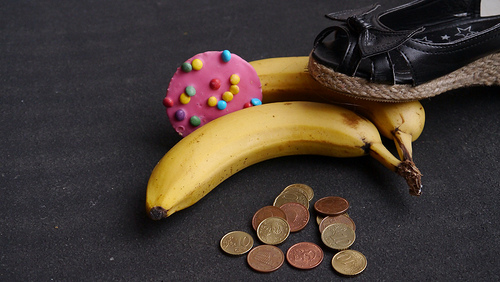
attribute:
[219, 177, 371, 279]
pennies — pile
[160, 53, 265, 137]
cookie — pink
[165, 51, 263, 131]
frosting — pink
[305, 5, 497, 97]
shoe — black, brown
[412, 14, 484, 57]
stars — white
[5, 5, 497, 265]
table — black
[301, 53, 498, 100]
trim — fabric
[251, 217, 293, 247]
coin — gold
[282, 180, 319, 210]
coin — gold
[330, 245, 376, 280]
coin — copper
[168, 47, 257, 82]
cupcake — half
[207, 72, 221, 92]
sprinkle — red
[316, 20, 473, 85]
shoe — black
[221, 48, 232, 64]
decoration — aqua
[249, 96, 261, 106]
decoration — aqua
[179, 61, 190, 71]
decoration — aqua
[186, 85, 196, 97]
decoration — aqua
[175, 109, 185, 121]
decoration — aqua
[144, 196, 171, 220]
bottom — black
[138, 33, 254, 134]
cookie — pink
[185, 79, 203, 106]
sprinkle — green